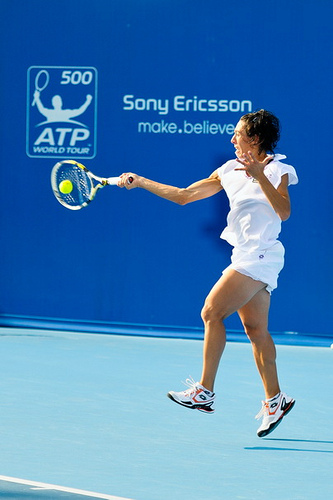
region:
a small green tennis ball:
[55, 180, 75, 194]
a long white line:
[1, 472, 121, 499]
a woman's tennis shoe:
[165, 385, 215, 418]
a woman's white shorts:
[228, 234, 287, 290]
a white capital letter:
[121, 91, 134, 115]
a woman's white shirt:
[213, 154, 300, 252]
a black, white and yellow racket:
[50, 157, 134, 210]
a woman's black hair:
[242, 109, 283, 161]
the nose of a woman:
[230, 134, 238, 144]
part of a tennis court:
[0, 322, 331, 498]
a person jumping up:
[52, 108, 295, 439]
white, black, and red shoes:
[171, 388, 293, 438]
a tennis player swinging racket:
[48, 109, 296, 439]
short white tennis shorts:
[227, 243, 285, 291]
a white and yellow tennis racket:
[51, 157, 130, 206]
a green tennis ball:
[57, 178, 71, 195]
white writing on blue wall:
[23, 63, 266, 183]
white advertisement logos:
[24, 63, 252, 162]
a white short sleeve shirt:
[216, 152, 296, 252]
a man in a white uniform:
[49, 109, 294, 437]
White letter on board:
[119, 87, 135, 114]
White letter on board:
[133, 96, 147, 112]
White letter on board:
[144, 97, 156, 112]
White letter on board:
[158, 98, 170, 117]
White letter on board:
[173, 95, 185, 113]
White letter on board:
[186, 97, 193, 116]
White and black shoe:
[157, 373, 222, 435]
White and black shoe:
[245, 379, 292, 442]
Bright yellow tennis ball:
[52, 179, 76, 201]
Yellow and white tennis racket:
[46, 144, 131, 219]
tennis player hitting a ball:
[38, 105, 301, 442]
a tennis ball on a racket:
[43, 150, 131, 211]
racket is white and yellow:
[46, 154, 139, 212]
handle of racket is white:
[104, 169, 137, 191]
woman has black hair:
[212, 98, 296, 198]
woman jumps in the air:
[43, 99, 308, 447]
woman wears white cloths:
[114, 103, 298, 294]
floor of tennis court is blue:
[0, 328, 328, 498]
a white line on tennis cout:
[2, 451, 121, 498]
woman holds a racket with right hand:
[35, 105, 307, 292]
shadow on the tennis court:
[291, 434, 331, 463]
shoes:
[163, 377, 213, 416]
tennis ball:
[57, 176, 73, 194]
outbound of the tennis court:
[28, 368, 133, 435]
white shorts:
[239, 253, 278, 277]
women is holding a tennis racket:
[97, 174, 133, 187]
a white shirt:
[224, 179, 259, 238]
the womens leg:
[250, 317, 288, 386]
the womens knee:
[199, 307, 213, 325]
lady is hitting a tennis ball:
[42, 109, 301, 422]